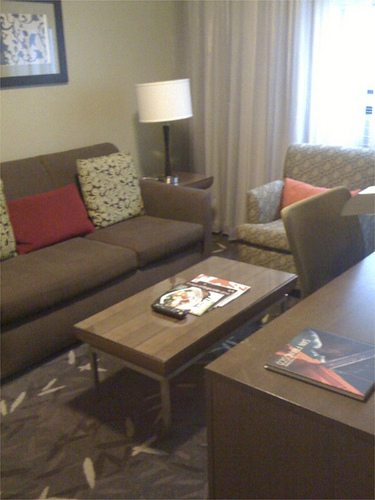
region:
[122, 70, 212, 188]
lamp with white shade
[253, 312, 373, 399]
book on a table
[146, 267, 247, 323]
group of books on table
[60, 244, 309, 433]
brown coffee table on floor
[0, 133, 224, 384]
brown couch with cushions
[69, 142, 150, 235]
cushion with floral pattern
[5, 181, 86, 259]
medium sized red cushion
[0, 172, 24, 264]
cushion with floral pattern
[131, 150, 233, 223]
brown wooden end table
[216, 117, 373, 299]
stuffed easy chair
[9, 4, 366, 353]
Small living room.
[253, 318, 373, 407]
Book sitting on a brown desk.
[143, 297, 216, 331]
Remote control for the tv.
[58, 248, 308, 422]
Brown coffee table in the living room.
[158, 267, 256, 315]
Magazines sitting on top of a coffee table.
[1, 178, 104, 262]
Red pillow sitting on the couch.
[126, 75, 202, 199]
Lamp with a white lampshade sitting on the end table.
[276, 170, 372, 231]
Orange pillow sitting in a chair.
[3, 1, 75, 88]
Picture hanging on the wall with a black frame.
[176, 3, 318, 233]
white curtains hanging in the window.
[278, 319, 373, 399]
book about San Francisco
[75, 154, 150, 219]
flowered throw cushion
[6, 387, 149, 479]
abstract patterned carpet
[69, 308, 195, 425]
coffee table with metal base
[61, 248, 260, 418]
coffee table with wood top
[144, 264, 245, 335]
magazines on coffee table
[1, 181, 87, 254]
red sofa throw cushion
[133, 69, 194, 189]
table lamp with white shade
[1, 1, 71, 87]
picture hanging over sofa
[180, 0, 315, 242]
beige full length curtains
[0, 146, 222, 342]
Brown living room couch.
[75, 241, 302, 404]
Wooden coffee table.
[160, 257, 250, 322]
Books and magazines for leisure reading.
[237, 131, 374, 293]
Living room lounge chair.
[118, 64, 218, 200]
Living room lamp with shade.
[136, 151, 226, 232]
Living room end table.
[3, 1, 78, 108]
Decorative living room painting.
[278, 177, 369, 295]
Desk chair for sitting at the desk.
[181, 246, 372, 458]
Office desk.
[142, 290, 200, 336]
Remote control for controlling a television.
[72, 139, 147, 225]
tan and brown patterned throw pillow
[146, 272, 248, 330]
magazines and remote sitting on a coffee table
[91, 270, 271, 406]
coffee table with magazines and remote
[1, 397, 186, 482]
tan and brown patterned carpet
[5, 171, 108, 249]
red throw pillow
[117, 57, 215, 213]
lamp on an end table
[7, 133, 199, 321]
brown couch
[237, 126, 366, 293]
tan and brown patterned chair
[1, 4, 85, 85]
black and white picture in a frame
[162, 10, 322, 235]
tan curtains